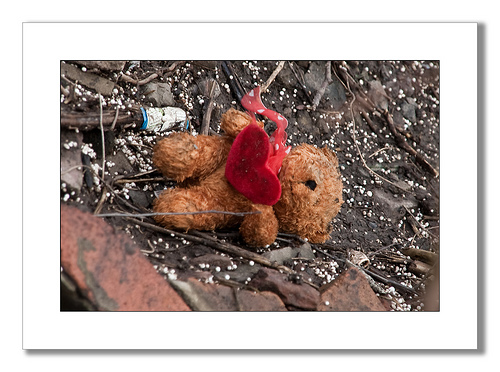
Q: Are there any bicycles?
A: No, there are no bicycles.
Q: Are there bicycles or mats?
A: No, there are no bicycles or mats.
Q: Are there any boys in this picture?
A: No, there are no boys.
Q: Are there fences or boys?
A: No, there are no boys or fences.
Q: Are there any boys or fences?
A: No, there are no boys or fences.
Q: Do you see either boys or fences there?
A: No, there are no boys or fences.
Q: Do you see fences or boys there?
A: No, there are no boys or fences.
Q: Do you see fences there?
A: No, there are no fences.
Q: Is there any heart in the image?
A: Yes, there is a heart.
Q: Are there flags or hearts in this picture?
A: Yes, there is a heart.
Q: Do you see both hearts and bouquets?
A: No, there is a heart but no bouquets.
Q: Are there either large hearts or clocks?
A: Yes, there is a large heart.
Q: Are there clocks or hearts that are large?
A: Yes, the heart is large.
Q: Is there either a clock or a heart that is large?
A: Yes, the heart is large.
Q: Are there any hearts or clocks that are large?
A: Yes, the heart is large.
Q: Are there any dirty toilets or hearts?
A: Yes, there is a dirty heart.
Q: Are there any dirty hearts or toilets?
A: Yes, there is a dirty heart.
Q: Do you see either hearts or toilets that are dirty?
A: Yes, the heart is dirty.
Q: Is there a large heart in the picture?
A: Yes, there is a large heart.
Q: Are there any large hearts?
A: Yes, there is a large heart.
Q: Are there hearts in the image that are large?
A: Yes, there is a heart that is large.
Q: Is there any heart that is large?
A: Yes, there is a heart that is large.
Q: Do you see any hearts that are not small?
A: Yes, there is a large heart.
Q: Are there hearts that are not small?
A: Yes, there is a large heart.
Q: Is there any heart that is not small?
A: Yes, there is a large heart.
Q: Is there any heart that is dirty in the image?
A: Yes, there is a dirty heart.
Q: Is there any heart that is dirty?
A: Yes, there is a heart that is dirty.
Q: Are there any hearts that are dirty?
A: Yes, there is a heart that is dirty.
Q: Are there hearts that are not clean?
A: Yes, there is a dirty heart.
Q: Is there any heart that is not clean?
A: Yes, there is a dirty heart.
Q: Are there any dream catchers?
A: No, there are no dream catchers.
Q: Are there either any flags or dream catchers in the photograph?
A: No, there are no dream catchers or flags.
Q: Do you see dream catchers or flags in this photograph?
A: No, there are no dream catchers or flags.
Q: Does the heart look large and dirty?
A: Yes, the heart is large and dirty.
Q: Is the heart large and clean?
A: No, the heart is large but dirty.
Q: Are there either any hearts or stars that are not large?
A: No, there is a heart but it is large.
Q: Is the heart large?
A: Yes, the heart is large.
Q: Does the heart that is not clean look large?
A: Yes, the heart is large.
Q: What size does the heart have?
A: The heart has large size.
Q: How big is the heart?
A: The heart is large.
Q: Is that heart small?
A: No, the heart is large.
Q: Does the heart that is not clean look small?
A: No, the heart is large.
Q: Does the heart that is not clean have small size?
A: No, the heart is large.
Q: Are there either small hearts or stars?
A: No, there is a heart but it is large.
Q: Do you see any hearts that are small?
A: No, there is a heart but it is large.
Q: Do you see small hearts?
A: No, there is a heart but it is large.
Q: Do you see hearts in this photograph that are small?
A: No, there is a heart but it is large.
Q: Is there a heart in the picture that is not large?
A: No, there is a heart but it is large.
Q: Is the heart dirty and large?
A: Yes, the heart is dirty and large.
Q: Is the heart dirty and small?
A: No, the heart is dirty but large.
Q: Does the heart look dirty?
A: Yes, the heart is dirty.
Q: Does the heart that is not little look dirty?
A: Yes, the heart is dirty.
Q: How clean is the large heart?
A: The heart is dirty.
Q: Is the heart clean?
A: No, the heart is dirty.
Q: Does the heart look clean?
A: No, the heart is dirty.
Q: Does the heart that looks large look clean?
A: No, the heart is dirty.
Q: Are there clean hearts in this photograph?
A: No, there is a heart but it is dirty.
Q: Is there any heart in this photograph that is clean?
A: No, there is a heart but it is dirty.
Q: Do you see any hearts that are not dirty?
A: No, there is a heart but it is dirty.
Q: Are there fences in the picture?
A: No, there are no fences.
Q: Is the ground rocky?
A: Yes, the ground is rocky.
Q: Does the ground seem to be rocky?
A: Yes, the ground is rocky.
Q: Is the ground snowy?
A: No, the ground is rocky.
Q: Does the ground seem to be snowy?
A: No, the ground is rocky.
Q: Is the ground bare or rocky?
A: The ground is rocky.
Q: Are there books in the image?
A: No, there are no books.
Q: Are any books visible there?
A: No, there are no books.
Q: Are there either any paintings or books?
A: No, there are no books or paintings.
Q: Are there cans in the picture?
A: Yes, there is a can.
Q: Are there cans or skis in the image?
A: Yes, there is a can.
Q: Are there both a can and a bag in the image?
A: No, there is a can but no bags.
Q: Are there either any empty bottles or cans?
A: Yes, there is an empty can.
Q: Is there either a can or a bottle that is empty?
A: Yes, the can is empty.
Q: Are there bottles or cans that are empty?
A: Yes, the can is empty.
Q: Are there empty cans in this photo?
A: Yes, there is an empty can.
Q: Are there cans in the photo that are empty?
A: Yes, there is a can that is empty.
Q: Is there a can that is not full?
A: Yes, there is a empty can.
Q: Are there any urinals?
A: No, there are no urinals.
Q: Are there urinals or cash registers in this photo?
A: No, there are no urinals or cash registers.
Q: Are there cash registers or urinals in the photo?
A: No, there are no urinals or cash registers.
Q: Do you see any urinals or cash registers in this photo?
A: No, there are no urinals or cash registers.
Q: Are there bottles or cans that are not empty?
A: No, there is a can but it is empty.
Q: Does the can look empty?
A: Yes, the can is empty.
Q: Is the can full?
A: No, the can is empty.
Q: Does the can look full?
A: No, the can is empty.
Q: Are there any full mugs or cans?
A: No, there is a can but it is empty.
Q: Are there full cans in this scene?
A: No, there is a can but it is empty.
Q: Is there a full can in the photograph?
A: No, there is a can but it is empty.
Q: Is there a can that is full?
A: No, there is a can but it is empty.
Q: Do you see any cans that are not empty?
A: No, there is a can but it is empty.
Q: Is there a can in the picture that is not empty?
A: No, there is a can but it is empty.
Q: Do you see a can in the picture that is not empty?
A: No, there is a can but it is empty.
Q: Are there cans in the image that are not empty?
A: No, there is a can but it is empty.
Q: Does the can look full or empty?
A: The can is empty.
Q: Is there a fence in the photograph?
A: No, there are no fences.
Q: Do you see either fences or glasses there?
A: No, there are no fences or glasses.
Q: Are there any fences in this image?
A: No, there are no fences.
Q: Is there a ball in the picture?
A: No, there are no balls.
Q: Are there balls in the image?
A: No, there are no balls.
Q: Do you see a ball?
A: No, there are no balls.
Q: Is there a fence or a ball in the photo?
A: No, there are no balls or fences.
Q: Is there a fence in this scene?
A: No, there are no fences.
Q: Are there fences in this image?
A: No, there are no fences.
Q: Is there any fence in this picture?
A: No, there are no fences.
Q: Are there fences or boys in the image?
A: No, there are no fences or boys.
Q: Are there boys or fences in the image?
A: No, there are no fences or boys.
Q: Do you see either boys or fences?
A: No, there are no fences or boys.